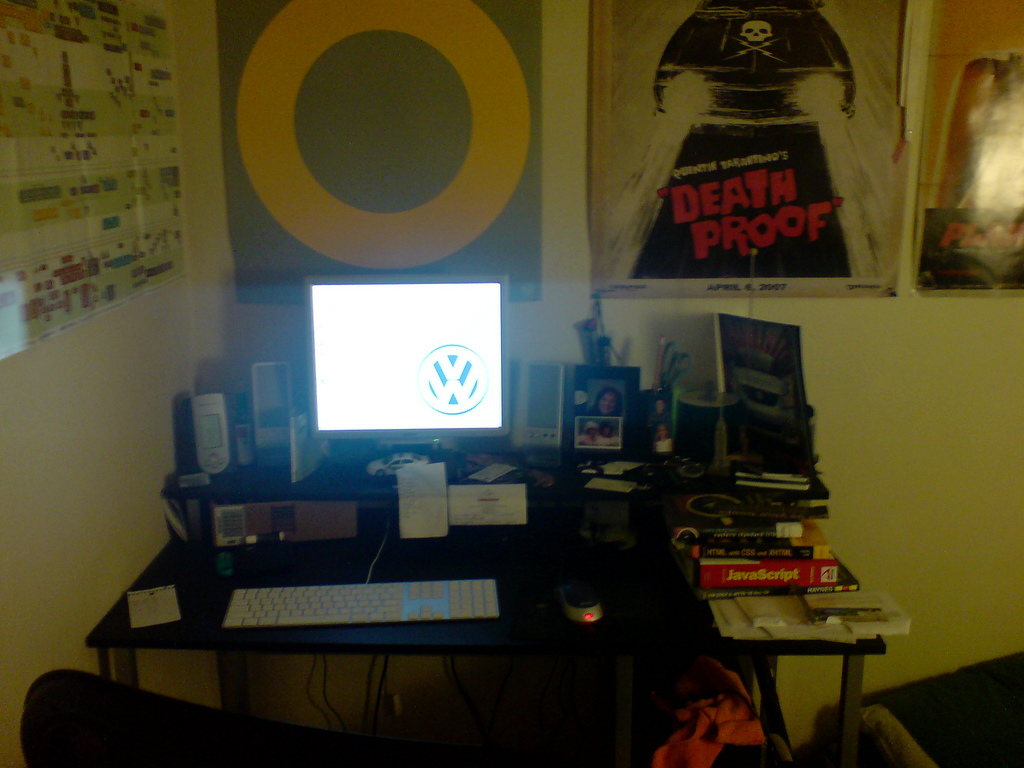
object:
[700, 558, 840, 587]
book binding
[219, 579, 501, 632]
keyboard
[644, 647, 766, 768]
bag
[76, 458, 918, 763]
desk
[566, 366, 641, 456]
picture frame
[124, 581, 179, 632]
notepad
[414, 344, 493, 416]
logo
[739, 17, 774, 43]
skull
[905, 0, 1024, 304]
poster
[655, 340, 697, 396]
scissors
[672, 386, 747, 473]
container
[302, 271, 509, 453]
monitor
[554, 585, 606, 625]
mouse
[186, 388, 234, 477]
speaker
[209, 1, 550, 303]
poster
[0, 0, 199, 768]
wall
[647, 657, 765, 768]
cloth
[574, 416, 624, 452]
picture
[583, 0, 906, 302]
poster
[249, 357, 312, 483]
speaker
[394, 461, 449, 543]
papers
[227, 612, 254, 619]
key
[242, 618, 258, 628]
key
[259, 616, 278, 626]
key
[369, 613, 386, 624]
key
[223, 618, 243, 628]
key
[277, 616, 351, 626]
key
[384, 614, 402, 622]
key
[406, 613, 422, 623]
key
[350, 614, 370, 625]
key